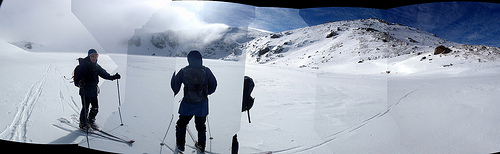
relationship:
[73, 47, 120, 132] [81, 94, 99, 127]
man wearing pants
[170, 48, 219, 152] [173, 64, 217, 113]
man wearing jacket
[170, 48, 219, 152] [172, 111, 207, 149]
man wearing black pants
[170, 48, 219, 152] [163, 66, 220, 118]
man wearing jacket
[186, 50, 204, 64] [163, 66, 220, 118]
hood on jacket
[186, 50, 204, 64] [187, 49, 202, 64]
hood on head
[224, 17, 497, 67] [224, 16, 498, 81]
snow on top of hill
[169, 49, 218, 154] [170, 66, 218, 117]
man wearing a jacket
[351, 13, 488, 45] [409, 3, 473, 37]
sky has some clouds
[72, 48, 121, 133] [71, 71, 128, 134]
man holding ski poles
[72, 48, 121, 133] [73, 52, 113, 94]
man wearing a coat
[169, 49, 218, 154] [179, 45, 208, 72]
man wearing a hood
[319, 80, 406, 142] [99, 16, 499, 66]
snow on a mountain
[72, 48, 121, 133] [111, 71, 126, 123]
man using poles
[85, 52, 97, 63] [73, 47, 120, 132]
head of a man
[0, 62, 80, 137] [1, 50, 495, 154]
snow tracks in snow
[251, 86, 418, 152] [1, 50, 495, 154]
snow tracks in snow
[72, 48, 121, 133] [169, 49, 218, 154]
man facing a man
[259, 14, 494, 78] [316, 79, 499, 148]
hill covered in snow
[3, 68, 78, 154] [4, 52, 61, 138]
tracks in snow